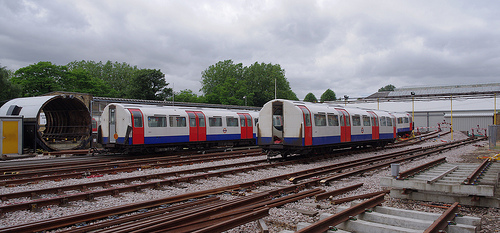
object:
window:
[131, 111, 144, 128]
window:
[301, 108, 313, 127]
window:
[187, 113, 197, 128]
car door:
[297, 105, 313, 146]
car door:
[127, 108, 145, 145]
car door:
[185, 110, 207, 141]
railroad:
[0, 149, 308, 233]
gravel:
[364, 178, 382, 192]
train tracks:
[0, 125, 499, 232]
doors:
[235, 113, 251, 139]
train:
[98, 102, 256, 154]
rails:
[313, 182, 390, 205]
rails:
[394, 157, 448, 180]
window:
[352, 116, 361, 126]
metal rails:
[132, 202, 274, 232]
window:
[314, 113, 327, 126]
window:
[147, 116, 168, 127]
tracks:
[135, 186, 324, 233]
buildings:
[362, 83, 500, 117]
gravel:
[231, 175, 244, 183]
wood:
[169, 183, 188, 190]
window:
[169, 115, 186, 127]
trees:
[201, 59, 300, 106]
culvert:
[0, 95, 94, 152]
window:
[209, 116, 222, 127]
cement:
[336, 201, 482, 233]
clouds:
[345, 4, 460, 59]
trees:
[0, 59, 178, 108]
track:
[0, 150, 266, 216]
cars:
[254, 99, 414, 162]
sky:
[0, 0, 497, 100]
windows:
[336, 110, 351, 127]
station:
[85, 96, 264, 143]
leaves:
[222, 66, 242, 83]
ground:
[0, 161, 499, 229]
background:
[0, 53, 500, 99]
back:
[256, 98, 302, 147]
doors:
[334, 108, 397, 143]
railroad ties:
[295, 202, 444, 233]